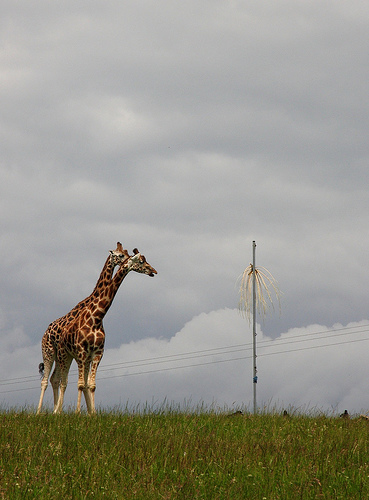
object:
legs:
[35, 351, 104, 416]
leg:
[75, 349, 94, 414]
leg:
[34, 345, 57, 418]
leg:
[53, 347, 74, 414]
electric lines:
[267, 327, 358, 351]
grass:
[3, 413, 367, 459]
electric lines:
[0, 324, 369, 394]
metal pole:
[252, 240, 257, 414]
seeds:
[52, 452, 66, 460]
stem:
[51, 448, 59, 456]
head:
[108, 241, 130, 267]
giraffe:
[53, 247, 157, 416]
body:
[36, 241, 158, 415]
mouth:
[149, 266, 158, 277]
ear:
[109, 250, 114, 255]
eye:
[119, 254, 124, 258]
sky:
[69, 81, 270, 193]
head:
[131, 247, 158, 277]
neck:
[89, 255, 132, 322]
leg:
[89, 346, 105, 413]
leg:
[35, 347, 74, 418]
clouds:
[9, 305, 365, 414]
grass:
[0, 395, 369, 499]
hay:
[235, 261, 286, 328]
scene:
[0, 0, 369, 494]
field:
[4, 407, 357, 497]